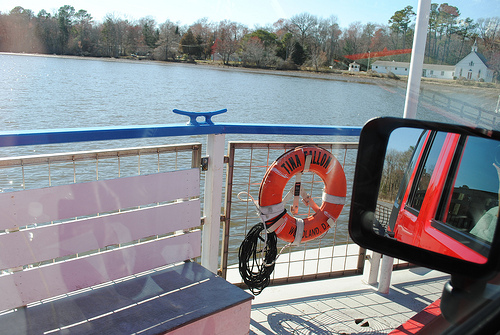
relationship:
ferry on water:
[1, 109, 497, 335] [0, 53, 499, 270]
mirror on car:
[347, 116, 499, 283] [347, 116, 498, 335]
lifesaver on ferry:
[256, 146, 347, 245] [1, 109, 497, 335]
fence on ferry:
[1, 166, 258, 334] [1, 109, 497, 335]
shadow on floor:
[249, 274, 449, 334] [227, 242, 451, 334]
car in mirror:
[347, 116, 498, 335] [347, 116, 499, 283]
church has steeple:
[453, 36, 495, 84] [472, 36, 479, 52]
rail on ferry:
[1, 108, 362, 148] [1, 109, 497, 335]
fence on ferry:
[1, 141, 422, 289] [1, 109, 497, 335]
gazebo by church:
[347, 60, 360, 73] [453, 36, 495, 84]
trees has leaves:
[1, 3, 499, 68] [211, 26, 253, 57]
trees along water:
[1, 3, 499, 68] [0, 53, 499, 270]